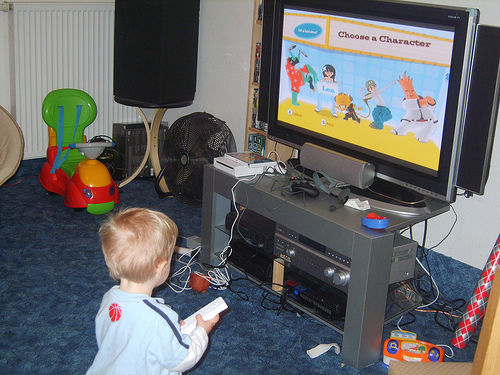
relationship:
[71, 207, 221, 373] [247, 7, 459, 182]
child use television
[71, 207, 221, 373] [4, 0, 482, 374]
child in living room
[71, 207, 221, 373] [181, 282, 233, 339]
child using a game controller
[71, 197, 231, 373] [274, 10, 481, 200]
child watching screen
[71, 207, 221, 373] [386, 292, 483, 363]
child playing videogame